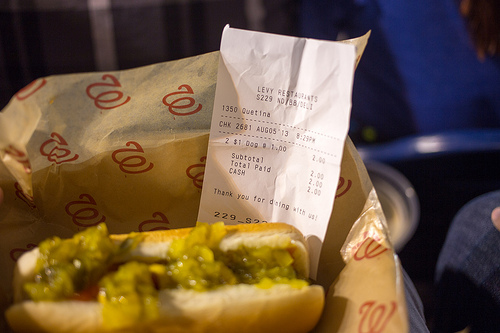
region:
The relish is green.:
[49, 242, 174, 282]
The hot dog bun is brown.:
[3, 223, 323, 328]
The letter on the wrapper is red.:
[105, 139, 160, 174]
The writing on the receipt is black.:
[243, 84, 325, 111]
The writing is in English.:
[257, 78, 324, 110]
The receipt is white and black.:
[203, 26, 355, 223]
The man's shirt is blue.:
[378, 6, 476, 119]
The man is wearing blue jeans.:
[426, 192, 498, 327]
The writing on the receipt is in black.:
[226, 149, 273, 184]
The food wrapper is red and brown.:
[41, 99, 183, 199]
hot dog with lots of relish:
[19, 234, 322, 324]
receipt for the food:
[191, 40, 346, 226]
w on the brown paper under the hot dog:
[106, 135, 158, 180]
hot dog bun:
[189, 296, 336, 317]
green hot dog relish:
[34, 239, 93, 293]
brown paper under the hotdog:
[8, 59, 168, 223]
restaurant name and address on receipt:
[251, 74, 326, 113]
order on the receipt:
[219, 98, 337, 209]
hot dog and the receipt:
[11, 92, 374, 331]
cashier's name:
[239, 103, 273, 122]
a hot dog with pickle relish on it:
[42, 190, 308, 328]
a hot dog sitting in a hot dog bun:
[43, 155, 423, 325]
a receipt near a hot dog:
[180, 60, 386, 251]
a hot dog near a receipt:
[30, 170, 347, 325]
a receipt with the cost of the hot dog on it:
[180, 27, 386, 232]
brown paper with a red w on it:
[56, 48, 286, 233]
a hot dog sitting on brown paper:
[32, 105, 369, 325]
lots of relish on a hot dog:
[32, 187, 373, 312]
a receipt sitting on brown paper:
[120, 40, 425, 221]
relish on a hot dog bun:
[67, 250, 215, 324]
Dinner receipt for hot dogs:
[195, 30, 370, 225]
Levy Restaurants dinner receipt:
[200, 40, 355, 225]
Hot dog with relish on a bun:
[0, 215, 310, 325]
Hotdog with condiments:
[0, 215, 325, 325]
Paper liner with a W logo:
[10, 60, 390, 325]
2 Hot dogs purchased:
[215, 130, 330, 205]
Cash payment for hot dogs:
[215, 135, 325, 195]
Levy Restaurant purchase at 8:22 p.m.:
[247, 78, 322, 148]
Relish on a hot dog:
[0, 215, 310, 315]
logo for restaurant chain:
[111, 128, 159, 180]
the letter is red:
[161, 81, 207, 118]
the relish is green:
[180, 235, 217, 277]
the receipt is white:
[238, 43, 268, 75]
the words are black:
[228, 99, 267, 163]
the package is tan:
[73, 109, 103, 144]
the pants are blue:
[459, 219, 481, 266]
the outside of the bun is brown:
[239, 221, 268, 231]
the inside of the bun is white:
[247, 231, 266, 248]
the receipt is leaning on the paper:
[183, 140, 223, 182]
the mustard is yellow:
[152, 262, 166, 279]